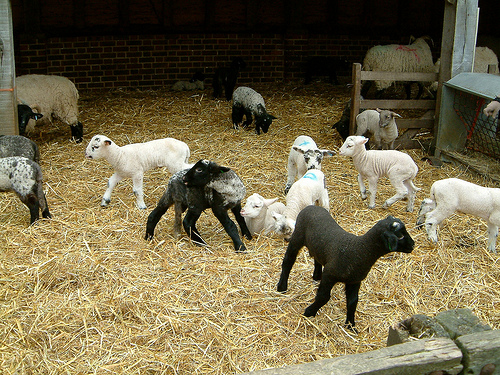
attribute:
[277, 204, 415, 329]
lamb — black, fenced, looking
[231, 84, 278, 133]
lamb — black, white, eating, grey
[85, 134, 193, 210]
lamb — small, white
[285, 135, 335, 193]
lamb — grooming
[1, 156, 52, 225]
lamb — grey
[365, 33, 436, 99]
sheep — tan, standing, grouped, animal, white, eating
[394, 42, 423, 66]
marking — red, blue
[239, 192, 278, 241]
lamb — lying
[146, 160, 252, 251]
sheep — looking, small, grooming, young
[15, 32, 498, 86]
wall — brick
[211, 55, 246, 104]
sheep — black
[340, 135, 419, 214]
sheep — white, grouped, stepping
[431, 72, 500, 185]
table — back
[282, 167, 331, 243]
lamb — eating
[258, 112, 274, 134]
head — black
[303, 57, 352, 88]
sheep — black